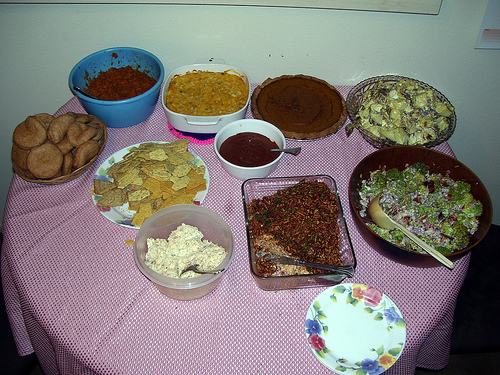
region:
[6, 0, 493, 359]
Many potluck dishes on a table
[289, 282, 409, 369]
Paper plates on a table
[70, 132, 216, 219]
Crackers on a table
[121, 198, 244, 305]
Chicken salad in a bowl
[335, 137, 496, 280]
Plenty of salad in a salad bowl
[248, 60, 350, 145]
Pie on a table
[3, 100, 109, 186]
Basket of rolls on a table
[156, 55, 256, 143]
Corn like food in a white container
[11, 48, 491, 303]
food on the table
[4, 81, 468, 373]
the table is round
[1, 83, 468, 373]
table cloth is red and white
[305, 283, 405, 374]
the plate is empty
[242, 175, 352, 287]
some kind of casserole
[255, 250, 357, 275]
the knife is sticking in the food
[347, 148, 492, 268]
a bowl of salad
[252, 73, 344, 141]
the pie is uneaten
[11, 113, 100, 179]
a pile of rolls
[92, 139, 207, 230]
chips on a plate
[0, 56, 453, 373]
food on top of table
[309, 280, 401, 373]
paper plate on table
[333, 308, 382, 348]
white center of paper plate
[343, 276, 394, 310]
flowers on rim of plate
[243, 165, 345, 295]
glass dish filled with food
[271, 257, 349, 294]
metal serving spoon in dish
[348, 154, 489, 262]
wooden bowl with salad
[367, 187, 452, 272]
plastic sever in salad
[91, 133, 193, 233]
food on top of plate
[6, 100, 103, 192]
pieces of bread in a bowl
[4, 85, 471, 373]
a red and white checked table cloth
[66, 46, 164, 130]
a large blue bowl on the table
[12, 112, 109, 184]
a basket full of bread on the table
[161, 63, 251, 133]
a white casserole dish on the table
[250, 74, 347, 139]
a pumpkin pie on the table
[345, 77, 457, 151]
a round glass bowl on the table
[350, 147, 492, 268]
a large wooden salad bowl on table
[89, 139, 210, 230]
crackers and cheese on a plate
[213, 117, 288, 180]
a round white bowl on the table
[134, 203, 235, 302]
a plastic tupperware bowl on table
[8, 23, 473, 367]
food on a table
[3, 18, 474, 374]
a pink table cloth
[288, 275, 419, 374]
a plate with roses on it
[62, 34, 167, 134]
a blue bowl with salsa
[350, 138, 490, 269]
a salad inside a bowl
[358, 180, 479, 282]
a wooden mixing spoon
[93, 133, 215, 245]
a plate of different crackers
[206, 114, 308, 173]
a silver spoon inside of a white bowl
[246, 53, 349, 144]
a pie sitting on a table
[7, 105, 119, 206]
bread inside of a basket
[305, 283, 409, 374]
white floral plate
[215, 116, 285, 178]
white bowl of salsa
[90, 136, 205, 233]
plate of brown chips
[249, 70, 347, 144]
brown round pie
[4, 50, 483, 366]
red checkered table cloth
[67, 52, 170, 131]
blue bowl of salsa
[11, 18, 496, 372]
Food on a table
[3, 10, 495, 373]
Food on a table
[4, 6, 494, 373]
Food on a table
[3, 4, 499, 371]
Food on a table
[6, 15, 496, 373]
Food on a table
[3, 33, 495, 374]
Food on a table